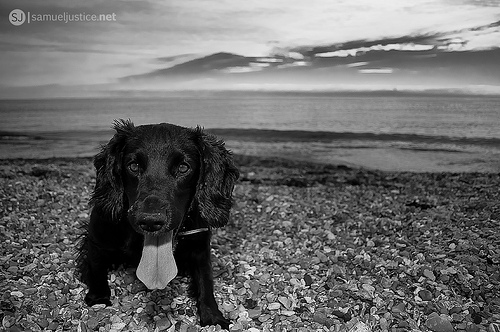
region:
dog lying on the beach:
[62, 114, 242, 322]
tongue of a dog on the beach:
[132, 226, 187, 298]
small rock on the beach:
[262, 298, 282, 313]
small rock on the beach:
[360, 279, 375, 299]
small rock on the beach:
[272, 293, 292, 310]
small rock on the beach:
[152, 314, 174, 330]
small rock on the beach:
[22, 284, 39, 298]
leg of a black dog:
[179, 229, 225, 330]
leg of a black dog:
[72, 245, 122, 312]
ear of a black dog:
[187, 132, 244, 224]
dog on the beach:
[57, 120, 238, 310]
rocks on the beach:
[297, 297, 335, 327]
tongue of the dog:
[138, 248, 180, 293]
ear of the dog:
[196, 170, 223, 230]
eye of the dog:
[170, 157, 196, 180]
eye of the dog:
[125, 157, 157, 172]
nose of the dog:
[135, 204, 175, 234]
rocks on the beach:
[338, 262, 373, 304]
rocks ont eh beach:
[327, 220, 350, 252]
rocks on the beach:
[328, 207, 347, 232]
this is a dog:
[111, 120, 193, 296]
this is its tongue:
[142, 246, 164, 290]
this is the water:
[262, 110, 340, 140]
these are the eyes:
[128, 162, 196, 178]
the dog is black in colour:
[115, 114, 197, 280]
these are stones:
[272, 237, 352, 329]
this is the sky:
[127, 32, 197, 61]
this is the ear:
[196, 135, 242, 220]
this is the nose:
[137, 196, 168, 233]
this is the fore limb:
[91, 225, 120, 311]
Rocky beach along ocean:
[5, 154, 497, 327]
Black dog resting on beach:
[75, 116, 237, 326]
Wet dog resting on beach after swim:
[76, 118, 237, 328]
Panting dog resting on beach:
[96, 119, 239, 291]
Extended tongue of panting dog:
[135, 233, 178, 291]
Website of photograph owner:
[5, 7, 119, 27]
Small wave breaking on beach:
[4, 129, 499, 142]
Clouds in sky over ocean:
[9, 1, 496, 98]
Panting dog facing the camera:
[76, 117, 238, 327]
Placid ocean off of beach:
[0, 99, 490, 169]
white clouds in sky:
[0, 3, 499, 90]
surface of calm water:
[3, 91, 493, 150]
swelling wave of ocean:
[39, 126, 496, 153]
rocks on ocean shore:
[3, 162, 498, 330]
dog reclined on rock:
[75, 121, 242, 328]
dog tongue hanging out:
[130, 229, 180, 290]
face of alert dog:
[121, 123, 204, 235]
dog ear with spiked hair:
[191, 125, 238, 228]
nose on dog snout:
[136, 211, 171, 231]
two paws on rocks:
[80, 270, 233, 328]